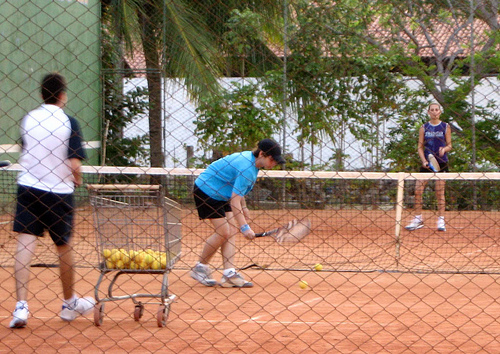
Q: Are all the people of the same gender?
A: No, they are both male and female.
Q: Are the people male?
A: No, they are both male and female.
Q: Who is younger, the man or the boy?
A: The boy is younger than the man.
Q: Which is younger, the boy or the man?
A: The boy is younger than the man.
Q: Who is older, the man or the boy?
A: The man is older than the boy.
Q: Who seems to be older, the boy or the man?
A: The man is older than the boy.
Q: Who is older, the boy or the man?
A: The man is older than the boy.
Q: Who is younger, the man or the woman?
A: The woman is younger than the man.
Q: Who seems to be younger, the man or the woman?
A: The woman is younger than the man.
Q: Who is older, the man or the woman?
A: The man is older than the woman.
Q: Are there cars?
A: No, there are no cars.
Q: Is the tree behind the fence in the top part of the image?
A: Yes, the tree is behind the fence.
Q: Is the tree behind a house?
A: No, the tree is behind the fence.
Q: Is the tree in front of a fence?
A: No, the tree is behind a fence.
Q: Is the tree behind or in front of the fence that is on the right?
A: The tree is behind the fence.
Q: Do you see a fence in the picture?
A: Yes, there is a fence.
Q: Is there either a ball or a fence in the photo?
A: Yes, there is a fence.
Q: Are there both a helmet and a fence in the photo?
A: No, there is a fence but no helmets.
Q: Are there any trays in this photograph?
A: No, there are no trays.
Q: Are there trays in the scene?
A: No, there are no trays.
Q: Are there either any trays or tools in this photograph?
A: No, there are no trays or tools.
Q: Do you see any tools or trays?
A: No, there are no trays or tools.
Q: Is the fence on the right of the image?
A: Yes, the fence is on the right of the image.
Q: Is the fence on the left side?
A: No, the fence is on the right of the image.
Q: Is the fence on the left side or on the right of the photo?
A: The fence is on the right of the image.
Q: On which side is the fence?
A: The fence is on the right of the image.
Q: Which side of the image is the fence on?
A: The fence is on the right of the image.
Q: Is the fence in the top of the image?
A: Yes, the fence is in the top of the image.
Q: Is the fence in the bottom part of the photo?
A: No, the fence is in the top of the image.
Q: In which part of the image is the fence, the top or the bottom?
A: The fence is in the top of the image.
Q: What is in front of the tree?
A: The fence is in front of the tree.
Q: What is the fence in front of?
A: The fence is in front of the tree.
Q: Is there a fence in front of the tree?
A: Yes, there is a fence in front of the tree.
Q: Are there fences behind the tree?
A: No, the fence is in front of the tree.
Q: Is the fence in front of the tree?
A: Yes, the fence is in front of the tree.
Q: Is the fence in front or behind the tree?
A: The fence is in front of the tree.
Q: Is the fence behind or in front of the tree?
A: The fence is in front of the tree.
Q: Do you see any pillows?
A: No, there are no pillows.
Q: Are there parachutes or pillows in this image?
A: No, there are no pillows or parachutes.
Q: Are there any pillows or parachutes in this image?
A: No, there are no pillows or parachutes.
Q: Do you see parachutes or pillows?
A: No, there are no pillows or parachutes.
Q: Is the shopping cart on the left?
A: Yes, the shopping cart is on the left of the image.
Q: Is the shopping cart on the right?
A: No, the shopping cart is on the left of the image.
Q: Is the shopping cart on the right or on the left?
A: The shopping cart is on the left of the image.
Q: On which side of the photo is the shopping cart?
A: The shopping cart is on the left of the image.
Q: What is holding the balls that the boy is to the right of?
A: The shopping cart is holding the balls.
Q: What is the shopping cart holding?
A: The shopping cart is holding the balls.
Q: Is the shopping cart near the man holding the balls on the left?
A: Yes, the shopping cart is holding the balls.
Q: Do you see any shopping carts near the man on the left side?
A: Yes, there is a shopping cart near the man.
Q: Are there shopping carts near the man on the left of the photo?
A: Yes, there is a shopping cart near the man.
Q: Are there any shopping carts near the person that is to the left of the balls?
A: Yes, there is a shopping cart near the man.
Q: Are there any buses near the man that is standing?
A: No, there is a shopping cart near the man.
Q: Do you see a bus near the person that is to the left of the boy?
A: No, there is a shopping cart near the man.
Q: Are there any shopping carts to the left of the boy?
A: Yes, there is a shopping cart to the left of the boy.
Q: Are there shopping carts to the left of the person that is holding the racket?
A: Yes, there is a shopping cart to the left of the boy.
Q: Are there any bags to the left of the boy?
A: No, there is a shopping cart to the left of the boy.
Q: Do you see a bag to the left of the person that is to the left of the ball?
A: No, there is a shopping cart to the left of the boy.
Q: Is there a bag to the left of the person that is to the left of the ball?
A: No, there is a shopping cart to the left of the boy.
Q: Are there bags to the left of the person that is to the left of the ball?
A: No, there is a shopping cart to the left of the boy.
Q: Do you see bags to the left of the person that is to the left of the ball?
A: No, there is a shopping cart to the left of the boy.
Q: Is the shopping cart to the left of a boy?
A: Yes, the shopping cart is to the left of a boy.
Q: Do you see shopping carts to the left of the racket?
A: Yes, there is a shopping cart to the left of the racket.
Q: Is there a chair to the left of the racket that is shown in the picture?
A: No, there is a shopping cart to the left of the racket.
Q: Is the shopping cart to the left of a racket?
A: Yes, the shopping cart is to the left of a racket.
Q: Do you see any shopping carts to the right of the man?
A: Yes, there is a shopping cart to the right of the man.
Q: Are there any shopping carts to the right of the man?
A: Yes, there is a shopping cart to the right of the man.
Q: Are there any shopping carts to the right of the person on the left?
A: Yes, there is a shopping cart to the right of the man.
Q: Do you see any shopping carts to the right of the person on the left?
A: Yes, there is a shopping cart to the right of the man.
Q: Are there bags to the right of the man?
A: No, there is a shopping cart to the right of the man.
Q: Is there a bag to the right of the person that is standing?
A: No, there is a shopping cart to the right of the man.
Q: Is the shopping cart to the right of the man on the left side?
A: Yes, the shopping cart is to the right of the man.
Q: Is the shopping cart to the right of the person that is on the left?
A: Yes, the shopping cart is to the right of the man.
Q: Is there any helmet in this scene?
A: No, there are no helmets.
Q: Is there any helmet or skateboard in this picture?
A: No, there are no helmets or skateboards.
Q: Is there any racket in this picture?
A: Yes, there is a racket.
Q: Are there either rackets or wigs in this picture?
A: Yes, there is a racket.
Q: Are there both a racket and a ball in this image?
A: Yes, there are both a racket and a ball.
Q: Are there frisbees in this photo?
A: No, there are no frisbees.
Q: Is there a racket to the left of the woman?
A: Yes, there is a racket to the left of the woman.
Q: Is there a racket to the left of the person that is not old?
A: Yes, there is a racket to the left of the woman.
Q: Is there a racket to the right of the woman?
A: No, the racket is to the left of the woman.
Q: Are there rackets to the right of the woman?
A: No, the racket is to the left of the woman.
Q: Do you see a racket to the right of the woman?
A: No, the racket is to the left of the woman.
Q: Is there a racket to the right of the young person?
A: No, the racket is to the left of the woman.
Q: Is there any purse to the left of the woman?
A: No, there is a racket to the left of the woman.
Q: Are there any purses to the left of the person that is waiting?
A: No, there is a racket to the left of the woman.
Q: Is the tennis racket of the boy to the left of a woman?
A: Yes, the tennis racket is to the left of a woman.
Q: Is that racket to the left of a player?
A: No, the racket is to the left of a woman.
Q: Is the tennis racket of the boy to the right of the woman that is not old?
A: No, the tennis racket is to the left of the woman.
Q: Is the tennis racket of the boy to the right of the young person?
A: No, the tennis racket is to the left of the woman.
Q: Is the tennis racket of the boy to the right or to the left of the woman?
A: The tennis racket is to the left of the woman.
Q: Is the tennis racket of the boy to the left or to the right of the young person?
A: The tennis racket is to the left of the woman.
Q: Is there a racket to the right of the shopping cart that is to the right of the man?
A: Yes, there is a racket to the right of the shopping cart.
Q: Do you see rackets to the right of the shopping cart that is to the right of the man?
A: Yes, there is a racket to the right of the shopping cart.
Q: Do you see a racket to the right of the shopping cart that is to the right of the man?
A: Yes, there is a racket to the right of the shopping cart.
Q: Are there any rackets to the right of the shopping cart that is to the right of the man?
A: Yes, there is a racket to the right of the shopping cart.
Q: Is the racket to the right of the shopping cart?
A: Yes, the racket is to the right of the shopping cart.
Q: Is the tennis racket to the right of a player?
A: No, the tennis racket is to the right of the shopping cart.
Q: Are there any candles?
A: No, there are no candles.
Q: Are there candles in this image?
A: No, there are no candles.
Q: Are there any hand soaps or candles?
A: No, there are no candles or hand soaps.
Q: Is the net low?
A: Yes, the net is low.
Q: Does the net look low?
A: Yes, the net is low.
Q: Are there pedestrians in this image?
A: No, there are no pedestrians.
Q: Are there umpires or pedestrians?
A: No, there are no pedestrians or umpires.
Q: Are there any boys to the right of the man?
A: Yes, there is a boy to the right of the man.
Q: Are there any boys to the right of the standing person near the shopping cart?
A: Yes, there is a boy to the right of the man.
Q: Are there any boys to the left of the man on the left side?
A: No, the boy is to the right of the man.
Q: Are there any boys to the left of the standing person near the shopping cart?
A: No, the boy is to the right of the man.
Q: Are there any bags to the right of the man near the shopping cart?
A: No, there is a boy to the right of the man.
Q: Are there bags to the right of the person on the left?
A: No, there is a boy to the right of the man.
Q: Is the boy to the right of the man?
A: Yes, the boy is to the right of the man.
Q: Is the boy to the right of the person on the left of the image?
A: Yes, the boy is to the right of the man.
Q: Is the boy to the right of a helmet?
A: No, the boy is to the right of the man.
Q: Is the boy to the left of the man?
A: No, the boy is to the right of the man.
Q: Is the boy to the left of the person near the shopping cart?
A: No, the boy is to the right of the man.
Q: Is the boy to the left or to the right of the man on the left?
A: The boy is to the right of the man.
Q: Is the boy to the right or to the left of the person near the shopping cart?
A: The boy is to the right of the man.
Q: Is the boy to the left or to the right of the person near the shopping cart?
A: The boy is to the right of the man.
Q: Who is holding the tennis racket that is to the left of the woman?
A: The boy is holding the tennis racket.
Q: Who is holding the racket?
A: The boy is holding the tennis racket.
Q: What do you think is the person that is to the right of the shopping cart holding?
A: The boy is holding the tennis racket.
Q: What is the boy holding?
A: The boy is holding the tennis racket.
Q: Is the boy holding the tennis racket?
A: Yes, the boy is holding the tennis racket.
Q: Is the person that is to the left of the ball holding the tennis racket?
A: Yes, the boy is holding the tennis racket.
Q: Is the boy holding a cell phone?
A: No, the boy is holding the tennis racket.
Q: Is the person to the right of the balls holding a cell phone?
A: No, the boy is holding the tennis racket.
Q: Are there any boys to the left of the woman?
A: Yes, there is a boy to the left of the woman.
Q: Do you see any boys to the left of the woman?
A: Yes, there is a boy to the left of the woman.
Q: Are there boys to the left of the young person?
A: Yes, there is a boy to the left of the woman.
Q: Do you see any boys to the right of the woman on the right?
A: No, the boy is to the left of the woman.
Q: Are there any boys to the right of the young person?
A: No, the boy is to the left of the woman.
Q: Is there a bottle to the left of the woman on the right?
A: No, there is a boy to the left of the woman.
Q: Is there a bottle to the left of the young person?
A: No, there is a boy to the left of the woman.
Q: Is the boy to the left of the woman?
A: Yes, the boy is to the left of the woman.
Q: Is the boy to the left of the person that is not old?
A: Yes, the boy is to the left of the woman.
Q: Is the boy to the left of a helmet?
A: No, the boy is to the left of the woman.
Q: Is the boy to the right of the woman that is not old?
A: No, the boy is to the left of the woman.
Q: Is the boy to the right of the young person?
A: No, the boy is to the left of the woman.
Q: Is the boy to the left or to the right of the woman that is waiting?
A: The boy is to the left of the woman.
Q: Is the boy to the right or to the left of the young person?
A: The boy is to the left of the woman.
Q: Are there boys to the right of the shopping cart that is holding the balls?
A: Yes, there is a boy to the right of the shopping cart.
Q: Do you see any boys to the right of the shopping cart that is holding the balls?
A: Yes, there is a boy to the right of the shopping cart.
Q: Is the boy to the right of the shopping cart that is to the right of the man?
A: Yes, the boy is to the right of the shopping cart.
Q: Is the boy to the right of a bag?
A: No, the boy is to the right of the shopping cart.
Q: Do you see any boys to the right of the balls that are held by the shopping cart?
A: Yes, there is a boy to the right of the balls.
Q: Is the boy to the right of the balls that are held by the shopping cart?
A: Yes, the boy is to the right of the balls.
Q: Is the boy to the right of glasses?
A: No, the boy is to the right of the balls.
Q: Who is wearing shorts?
A: The boy is wearing shorts.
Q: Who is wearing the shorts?
A: The boy is wearing shorts.